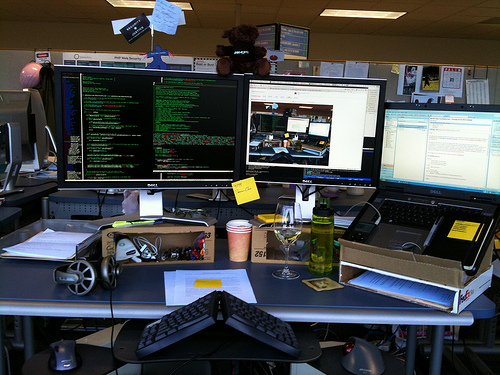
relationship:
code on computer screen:
[59, 70, 240, 183] [238, 72, 387, 189]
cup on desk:
[224, 207, 260, 276] [0, 197, 497, 375]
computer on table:
[53, 62, 243, 231] [2, 220, 478, 372]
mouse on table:
[53, 329, 99, 368] [2, 219, 477, 335]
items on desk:
[52, 197, 470, 298] [13, 164, 492, 321]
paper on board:
[466, 78, 493, 101] [391, 62, 478, 102]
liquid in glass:
[275, 228, 301, 245] [273, 201, 303, 281]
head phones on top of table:
[53, 254, 124, 296] [1, 208, 481, 364]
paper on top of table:
[2, 219, 101, 266] [2, 220, 478, 372]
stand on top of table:
[102, 219, 219, 270] [2, 220, 478, 372]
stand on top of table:
[242, 217, 344, 273] [2, 220, 478, 372]